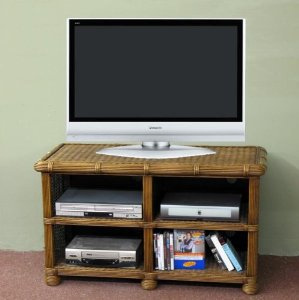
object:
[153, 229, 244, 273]
books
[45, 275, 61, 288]
stand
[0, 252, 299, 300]
floor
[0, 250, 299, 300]
carpet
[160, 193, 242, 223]
dvd player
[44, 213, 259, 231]
shelf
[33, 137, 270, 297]
table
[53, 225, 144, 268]
drawer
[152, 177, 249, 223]
drawer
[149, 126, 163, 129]
logo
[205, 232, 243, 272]
tape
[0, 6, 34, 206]
wall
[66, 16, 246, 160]
tv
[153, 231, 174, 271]
dvd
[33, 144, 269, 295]
television stand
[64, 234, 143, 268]
vhs player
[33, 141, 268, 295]
entertainment unit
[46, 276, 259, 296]
underneath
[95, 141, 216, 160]
stand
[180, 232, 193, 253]
man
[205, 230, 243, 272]
video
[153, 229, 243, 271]
collection